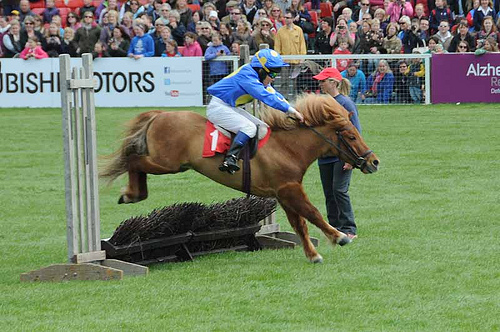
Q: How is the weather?
A: Clear.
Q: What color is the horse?
A: Brown.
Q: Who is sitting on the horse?
A: A jockey.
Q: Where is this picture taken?
A: A competition.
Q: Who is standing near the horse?
A: A woman.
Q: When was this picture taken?
A: Daytime.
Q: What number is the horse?
A: 1.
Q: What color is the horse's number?
A: Red and white.